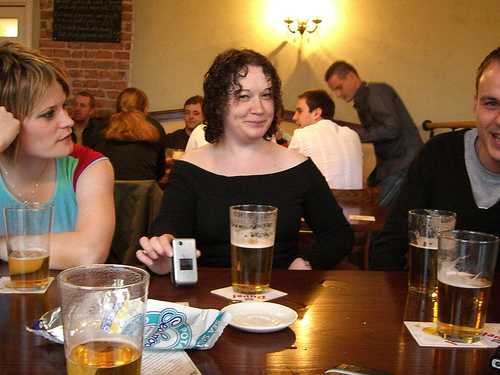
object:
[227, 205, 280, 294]
cup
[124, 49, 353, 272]
people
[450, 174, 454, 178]
ground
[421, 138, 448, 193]
ground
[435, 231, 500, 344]
glass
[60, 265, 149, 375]
glass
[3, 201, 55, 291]
glass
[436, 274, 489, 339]
liquid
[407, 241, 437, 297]
liquid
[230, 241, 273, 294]
liquid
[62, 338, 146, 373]
liquid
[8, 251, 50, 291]
liquid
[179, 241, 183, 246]
camera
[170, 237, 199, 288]
mobile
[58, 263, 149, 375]
cup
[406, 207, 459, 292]
glass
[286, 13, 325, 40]
bulbs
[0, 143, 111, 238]
green shirt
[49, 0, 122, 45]
blackboard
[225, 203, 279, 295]
glass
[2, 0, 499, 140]
wall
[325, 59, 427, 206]
people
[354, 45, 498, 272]
people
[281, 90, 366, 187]
people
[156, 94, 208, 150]
people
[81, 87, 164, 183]
people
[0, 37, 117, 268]
woman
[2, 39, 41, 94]
hair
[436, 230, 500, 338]
cups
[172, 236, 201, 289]
cell phone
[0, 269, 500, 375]
table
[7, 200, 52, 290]
cup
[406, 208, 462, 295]
glasses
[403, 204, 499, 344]
series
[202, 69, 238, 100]
hair